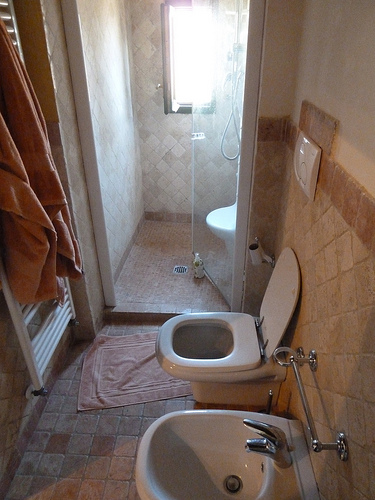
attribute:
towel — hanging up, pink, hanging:
[90, 330, 182, 426]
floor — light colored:
[65, 434, 117, 485]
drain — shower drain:
[169, 255, 204, 293]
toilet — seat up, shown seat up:
[162, 307, 290, 386]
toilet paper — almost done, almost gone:
[245, 224, 274, 275]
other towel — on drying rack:
[7, 40, 78, 286]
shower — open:
[84, 21, 261, 309]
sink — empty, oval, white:
[134, 404, 328, 493]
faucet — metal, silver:
[236, 419, 298, 484]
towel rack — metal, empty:
[3, 11, 28, 47]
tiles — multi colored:
[45, 418, 114, 432]